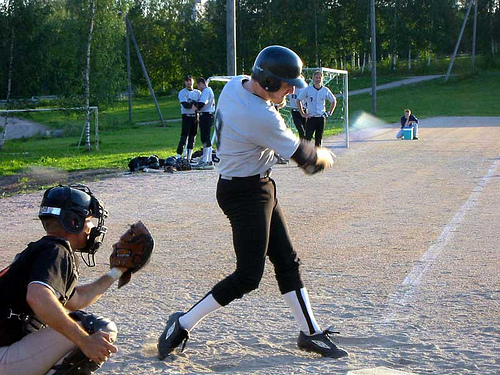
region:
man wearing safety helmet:
[244, 39, 308, 113]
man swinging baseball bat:
[155, 41, 355, 373]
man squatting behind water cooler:
[394, 106, 421, 142]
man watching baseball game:
[295, 69, 342, 151]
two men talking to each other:
[174, 73, 219, 169]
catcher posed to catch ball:
[0, 181, 163, 373]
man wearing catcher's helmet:
[34, 178, 108, 273]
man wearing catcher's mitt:
[1, 177, 161, 372]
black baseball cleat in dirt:
[288, 324, 353, 362]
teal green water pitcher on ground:
[401, 125, 416, 142]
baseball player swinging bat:
[195, 42, 401, 198]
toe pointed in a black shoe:
[137, 300, 217, 362]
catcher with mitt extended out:
[20, 170, 156, 296]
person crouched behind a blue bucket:
[380, 97, 435, 162]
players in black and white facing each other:
[161, 55, 212, 175]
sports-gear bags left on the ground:
[105, 141, 197, 176]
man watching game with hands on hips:
[291, 36, 361, 151]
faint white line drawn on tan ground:
[380, 135, 495, 350]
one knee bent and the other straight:
[201, 230, 327, 310]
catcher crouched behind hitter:
[3, 40, 344, 351]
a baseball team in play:
[3, 10, 467, 350]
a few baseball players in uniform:
[168, 36, 355, 165]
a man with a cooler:
[393, 93, 428, 160]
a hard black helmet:
[243, 37, 320, 105]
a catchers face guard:
[64, 163, 119, 268]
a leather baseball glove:
[109, 213, 159, 293]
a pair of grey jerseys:
[170, 83, 234, 128]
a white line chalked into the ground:
[373, 172, 498, 312]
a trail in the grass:
[343, 56, 469, 106]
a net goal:
[231, 47, 370, 156]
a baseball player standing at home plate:
[154, 43, 343, 368]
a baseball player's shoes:
[139, 309, 351, 362]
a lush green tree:
[44, 4, 121, 105]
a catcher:
[2, 179, 157, 374]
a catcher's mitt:
[108, 220, 153, 285]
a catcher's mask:
[82, 195, 105, 270]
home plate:
[336, 366, 419, 374]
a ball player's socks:
[179, 289, 316, 334]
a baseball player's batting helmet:
[252, 42, 312, 88]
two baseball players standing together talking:
[177, 76, 214, 175]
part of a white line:
[383, 243, 436, 295]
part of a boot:
[311, 344, 340, 361]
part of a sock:
[195, 307, 215, 324]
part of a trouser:
[239, 204, 278, 256]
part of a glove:
[122, 241, 161, 286]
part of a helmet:
[58, 198, 89, 233]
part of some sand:
[374, 334, 400, 352]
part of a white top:
[231, 128, 271, 176]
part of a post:
[335, 102, 358, 142]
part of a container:
[398, 120, 416, 139]